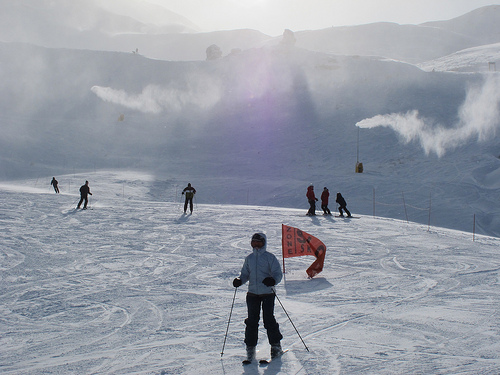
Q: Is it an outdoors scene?
A: Yes, it is outdoors.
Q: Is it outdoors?
A: Yes, it is outdoors.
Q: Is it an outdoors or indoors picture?
A: It is outdoors.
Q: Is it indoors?
A: No, it is outdoors.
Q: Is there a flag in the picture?
A: Yes, there is a flag.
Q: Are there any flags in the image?
A: Yes, there is a flag.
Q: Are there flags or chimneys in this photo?
A: Yes, there is a flag.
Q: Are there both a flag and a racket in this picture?
A: No, there is a flag but no rackets.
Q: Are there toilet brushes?
A: No, there are no toilet brushes.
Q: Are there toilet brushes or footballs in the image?
A: No, there are no toilet brushes or footballs.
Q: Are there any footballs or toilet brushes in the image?
A: No, there are no toilet brushes or footballs.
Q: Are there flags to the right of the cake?
A: Yes, there is a flag to the right of the cake.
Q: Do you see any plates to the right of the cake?
A: No, there is a flag to the right of the cake.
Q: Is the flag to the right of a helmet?
A: No, the flag is to the right of a cake.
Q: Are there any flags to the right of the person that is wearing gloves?
A: Yes, there is a flag to the right of the person.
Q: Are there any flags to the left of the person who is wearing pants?
A: No, the flag is to the right of the person.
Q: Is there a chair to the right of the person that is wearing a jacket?
A: No, there is a flag to the right of the person.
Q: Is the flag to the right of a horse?
A: No, the flag is to the right of the person.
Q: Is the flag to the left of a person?
A: No, the flag is to the right of a person.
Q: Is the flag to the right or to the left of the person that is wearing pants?
A: The flag is to the right of the person.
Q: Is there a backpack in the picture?
A: No, there are no backpacks.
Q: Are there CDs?
A: No, there are no cds.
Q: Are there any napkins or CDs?
A: No, there are no CDs or napkins.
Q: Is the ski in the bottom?
A: Yes, the ski is in the bottom of the image.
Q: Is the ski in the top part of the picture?
A: No, the ski is in the bottom of the image.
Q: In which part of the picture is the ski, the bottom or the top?
A: The ski is in the bottom of the image.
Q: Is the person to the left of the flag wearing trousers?
A: Yes, the person is wearing trousers.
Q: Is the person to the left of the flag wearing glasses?
A: No, the person is wearing trousers.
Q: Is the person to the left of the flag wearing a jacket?
A: Yes, the person is wearing a jacket.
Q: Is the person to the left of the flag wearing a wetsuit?
A: No, the person is wearing a jacket.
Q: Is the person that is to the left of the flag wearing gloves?
A: Yes, the person is wearing gloves.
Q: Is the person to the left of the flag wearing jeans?
A: No, the person is wearing gloves.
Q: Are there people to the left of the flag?
A: Yes, there is a person to the left of the flag.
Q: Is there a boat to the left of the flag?
A: No, there is a person to the left of the flag.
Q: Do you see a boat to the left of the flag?
A: No, there is a person to the left of the flag.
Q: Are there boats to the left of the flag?
A: No, there is a person to the left of the flag.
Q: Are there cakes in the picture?
A: Yes, there is a cake.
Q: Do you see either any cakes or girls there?
A: Yes, there is a cake.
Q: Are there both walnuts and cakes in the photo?
A: No, there is a cake but no walnuts.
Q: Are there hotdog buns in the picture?
A: No, there are no hotdog buns.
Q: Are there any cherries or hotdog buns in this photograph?
A: No, there are no hotdog buns or cherries.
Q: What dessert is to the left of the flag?
A: The dessert is a cake.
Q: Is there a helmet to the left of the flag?
A: No, there is a cake to the left of the flag.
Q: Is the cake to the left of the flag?
A: Yes, the cake is to the left of the flag.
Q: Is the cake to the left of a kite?
A: No, the cake is to the left of the flag.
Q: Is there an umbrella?
A: No, there are no umbrellas.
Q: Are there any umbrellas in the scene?
A: No, there are no umbrellas.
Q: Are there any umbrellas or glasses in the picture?
A: No, there are no umbrellas or glasses.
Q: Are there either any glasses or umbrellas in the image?
A: No, there are no umbrellas or glasses.